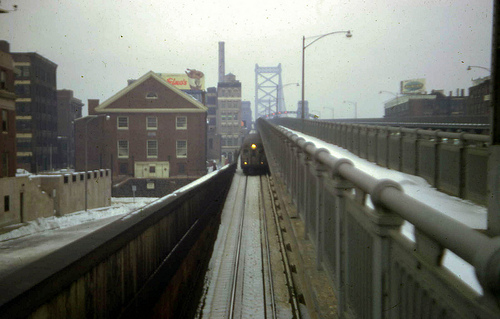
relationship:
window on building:
[143, 91, 160, 100] [69, 77, 209, 187]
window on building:
[143, 91, 160, 100] [81, 33, 211, 224]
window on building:
[115, 138, 126, 158] [81, 33, 211, 224]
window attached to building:
[143, 91, 160, 100] [96, 67, 209, 194]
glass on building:
[143, 111, 160, 132] [91, 70, 219, 196]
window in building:
[143, 91, 160, 100] [95, 71, 205, 198]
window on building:
[143, 91, 160, 100] [90, 68, 211, 179]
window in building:
[143, 91, 160, 100] [183, 40, 263, 168]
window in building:
[143, 91, 160, 100] [94, 61, 217, 190]